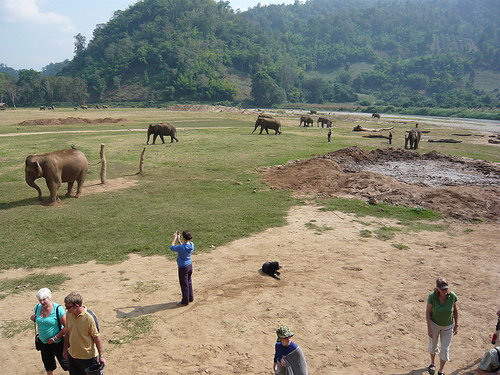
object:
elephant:
[144, 123, 178, 145]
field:
[0, 109, 498, 375]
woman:
[168, 230, 194, 307]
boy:
[271, 325, 309, 375]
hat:
[274, 326, 295, 343]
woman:
[424, 276, 458, 375]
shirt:
[424, 290, 458, 326]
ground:
[0, 263, 499, 375]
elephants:
[250, 118, 282, 136]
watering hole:
[266, 146, 499, 214]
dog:
[260, 261, 282, 281]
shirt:
[169, 242, 197, 267]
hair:
[181, 230, 192, 241]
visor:
[434, 278, 449, 290]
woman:
[29, 287, 67, 374]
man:
[60, 293, 107, 375]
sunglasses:
[65, 305, 77, 309]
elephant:
[24, 150, 87, 207]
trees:
[248, 67, 289, 109]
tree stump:
[99, 142, 108, 183]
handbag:
[34, 302, 40, 352]